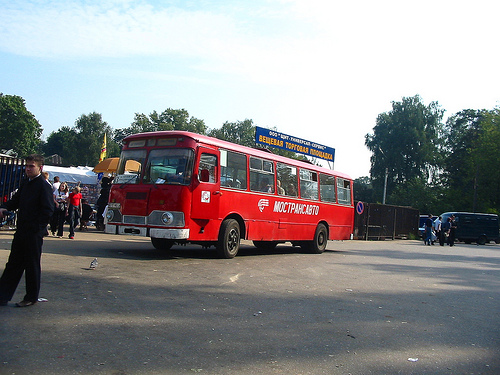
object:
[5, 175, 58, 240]
black coat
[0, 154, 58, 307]
man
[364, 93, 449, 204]
tree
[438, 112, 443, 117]
green leaves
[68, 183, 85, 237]
person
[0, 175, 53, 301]
clothing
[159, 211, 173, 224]
headlight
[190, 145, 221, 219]
door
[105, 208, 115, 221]
headlight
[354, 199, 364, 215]
sign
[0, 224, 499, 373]
parking lot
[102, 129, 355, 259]
bus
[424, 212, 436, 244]
people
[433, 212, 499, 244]
van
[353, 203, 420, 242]
fence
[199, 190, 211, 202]
sign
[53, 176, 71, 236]
person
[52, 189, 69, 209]
shirt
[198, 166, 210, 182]
sideview mirror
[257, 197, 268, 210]
design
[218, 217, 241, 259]
tire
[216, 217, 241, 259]
black tire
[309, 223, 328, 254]
tire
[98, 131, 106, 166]
flag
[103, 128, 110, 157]
pole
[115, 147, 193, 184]
front windshield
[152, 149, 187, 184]
window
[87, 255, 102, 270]
bird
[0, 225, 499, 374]
pavement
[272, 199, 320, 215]
writing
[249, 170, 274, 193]
window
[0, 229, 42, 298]
pants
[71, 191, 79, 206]
shirt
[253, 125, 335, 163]
banner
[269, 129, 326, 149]
writing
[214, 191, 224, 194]
handle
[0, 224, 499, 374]
ground